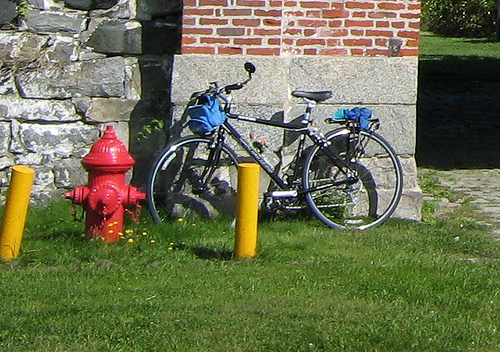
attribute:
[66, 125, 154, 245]
hydrant — red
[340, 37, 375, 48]
brick — red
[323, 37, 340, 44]
brick — red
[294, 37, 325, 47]
brick — red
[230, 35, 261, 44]
brick — red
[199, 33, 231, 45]
brick — red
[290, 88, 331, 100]
seat — black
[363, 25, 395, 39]
brick — red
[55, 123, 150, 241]
hydrant — red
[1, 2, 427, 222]
building — red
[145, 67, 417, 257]
bicycle — black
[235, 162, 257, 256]
pole — short, yellow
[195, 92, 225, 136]
bag(bad) — small, blue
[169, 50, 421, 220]
wall — rock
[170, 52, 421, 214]
blocks — gray, concrete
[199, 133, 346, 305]
poles — yellow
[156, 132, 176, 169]
reflector — white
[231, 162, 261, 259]
pole — metal, yellow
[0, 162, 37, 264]
pole — short, yellow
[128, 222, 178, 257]
flower — yellow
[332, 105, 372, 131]
cloth — blue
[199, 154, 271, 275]
post — yellow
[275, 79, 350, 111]
seat — black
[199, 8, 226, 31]
bricks — red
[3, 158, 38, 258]
post — yellow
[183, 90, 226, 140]
bag — for lunch, blue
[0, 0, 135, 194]
stones — large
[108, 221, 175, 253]
flowers — yellow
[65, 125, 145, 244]
fire hydrant — red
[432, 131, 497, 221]
driveway — dirt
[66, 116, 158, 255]
hydrant — red 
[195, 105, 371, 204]
frame — black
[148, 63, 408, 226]
bicycle — black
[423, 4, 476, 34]
shrubs — green